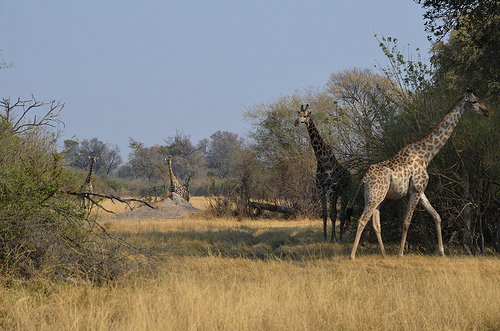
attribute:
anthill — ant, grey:
[130, 191, 194, 222]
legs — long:
[348, 193, 373, 260]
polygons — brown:
[375, 160, 449, 188]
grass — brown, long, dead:
[0, 195, 499, 330]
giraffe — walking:
[351, 85, 477, 256]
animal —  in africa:
[342, 84, 492, 260]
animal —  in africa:
[292, 102, 352, 241]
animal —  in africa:
[162, 156, 187, 196]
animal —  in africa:
[77, 153, 97, 215]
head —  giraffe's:
[293, 103, 310, 125]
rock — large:
[108, 190, 198, 220]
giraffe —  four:
[350, 89, 489, 257]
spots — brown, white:
[388, 158, 413, 177]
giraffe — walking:
[291, 103, 355, 245]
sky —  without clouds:
[0, 1, 472, 138]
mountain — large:
[418, 0, 495, 249]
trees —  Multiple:
[0, 95, 318, 291]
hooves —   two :
[335, 212, 458, 289]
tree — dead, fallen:
[235, 170, 298, 220]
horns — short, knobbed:
[298, 104, 311, 112]